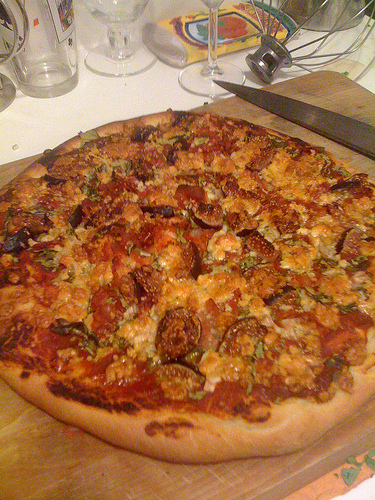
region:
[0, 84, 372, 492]
a freshly baked pizza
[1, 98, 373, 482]
a fresh hot pizza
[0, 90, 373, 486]
a freshly baked homemade pizza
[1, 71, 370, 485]
a home baked pizza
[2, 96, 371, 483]
a fresh home baked pizza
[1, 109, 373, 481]
a fresh home baked pizza on a cutting board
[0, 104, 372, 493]
a baked pizza on a cutting board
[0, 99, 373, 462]
a fresh homemade pizza on a cutting board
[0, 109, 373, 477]
a pizza on a wooden cutting board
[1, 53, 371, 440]
a pizza and a knife on a wooden cutting board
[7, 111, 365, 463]
a pizza is set here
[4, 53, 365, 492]
the pizza is on a wooden surface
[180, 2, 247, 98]
a wine glass stem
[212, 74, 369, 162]
the blade of a knife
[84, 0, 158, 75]
another glass is set in this area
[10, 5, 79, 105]
a glass displays the jack of cloves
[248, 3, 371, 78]
a whisk is on the counter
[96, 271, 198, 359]
one of the pizza toppings is pepperoni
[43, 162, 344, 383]
the pizza appears to be well done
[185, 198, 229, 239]
mushrooms are a topping on the pizza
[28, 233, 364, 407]
a pizza covered with toppings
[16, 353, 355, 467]
a thick crust style pizza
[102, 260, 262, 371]
melted cheese and peperoni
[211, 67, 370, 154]
a blade next to the pizza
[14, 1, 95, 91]
a glass on the counter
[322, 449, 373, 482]
a leaf beside the pizza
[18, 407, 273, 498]
a cutting board under the pizza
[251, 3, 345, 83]
a whisk on the counter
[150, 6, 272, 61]
a picture of a tomato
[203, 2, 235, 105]
the stem on a wine glass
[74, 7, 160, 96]
a glass on a table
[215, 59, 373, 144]
a knife on a cutting board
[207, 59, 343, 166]
a knife near a pizza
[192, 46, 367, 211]
a knife on a table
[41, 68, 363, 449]
a pizza on a table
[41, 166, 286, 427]
a cheese pizza on a cutting board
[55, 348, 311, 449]
the crust on a pizza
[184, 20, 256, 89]
the bottom of a wine glass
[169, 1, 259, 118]
a wine glass on a table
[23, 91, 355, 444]
a big cheese pizza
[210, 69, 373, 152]
The blade of a large knife.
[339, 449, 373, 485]
Oregano on the table.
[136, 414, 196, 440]
A brown spot on the pizza crust.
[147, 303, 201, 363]
A burnt mushroom on the pizza.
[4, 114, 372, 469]
A whole pizza on a cutting board.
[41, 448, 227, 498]
Knife marks and cuts on the cutting board.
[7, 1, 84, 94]
A pint glass with a playing card image on it.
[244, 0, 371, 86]
A large metal whisk.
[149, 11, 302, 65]
A green and yellow package with a picture of a tomato.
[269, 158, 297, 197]
Yellow cheese melted on the pizza.